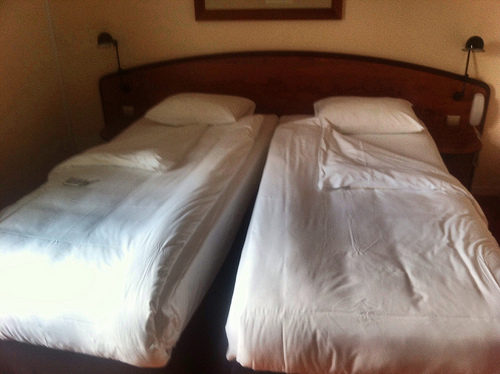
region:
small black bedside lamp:
[449, 21, 481, 106]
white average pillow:
[312, 95, 423, 145]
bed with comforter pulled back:
[287, 98, 450, 200]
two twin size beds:
[20, 66, 482, 363]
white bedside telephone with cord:
[461, 75, 483, 136]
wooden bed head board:
[90, 48, 499, 155]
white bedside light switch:
[441, 105, 461, 130]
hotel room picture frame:
[182, 2, 352, 27]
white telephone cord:
[467, 122, 494, 153]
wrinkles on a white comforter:
[414, 192, 491, 294]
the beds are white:
[24, 94, 483, 361]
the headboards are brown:
[76, 11, 460, 165]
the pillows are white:
[135, 80, 475, 165]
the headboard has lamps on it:
[73, 10, 495, 134]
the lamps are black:
[73, 22, 490, 161]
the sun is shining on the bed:
[3, 176, 183, 362]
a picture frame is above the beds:
[188, 0, 425, 57]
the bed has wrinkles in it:
[310, 168, 495, 310]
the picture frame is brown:
[190, 2, 435, 62]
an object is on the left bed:
[53, 159, 130, 219]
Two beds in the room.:
[5, 20, 495, 359]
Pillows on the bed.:
[144, 80, 421, 137]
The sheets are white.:
[2, 82, 494, 359]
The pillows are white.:
[137, 76, 436, 139]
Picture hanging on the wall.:
[180, 0, 359, 22]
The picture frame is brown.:
[188, 2, 346, 24]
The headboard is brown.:
[73, 32, 489, 162]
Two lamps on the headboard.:
[87, 14, 483, 79]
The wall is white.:
[5, 2, 107, 159]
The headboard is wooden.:
[87, 40, 492, 172]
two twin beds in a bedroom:
[6, 5, 498, 369]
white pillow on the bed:
[302, 91, 434, 136]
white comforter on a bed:
[262, 153, 487, 372]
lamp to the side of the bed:
[449, 23, 499, 85]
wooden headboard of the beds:
[147, 44, 452, 94]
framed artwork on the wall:
[179, 1, 366, 28]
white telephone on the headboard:
[468, 87, 489, 142]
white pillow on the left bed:
[149, 87, 254, 137]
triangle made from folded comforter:
[309, 129, 458, 205]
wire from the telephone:
[466, 129, 498, 164]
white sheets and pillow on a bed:
[271, 94, 498, 357]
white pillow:
[312, 95, 423, 135]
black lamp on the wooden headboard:
[448, 35, 484, 101]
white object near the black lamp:
[452, 34, 486, 130]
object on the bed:
[56, 171, 106, 191]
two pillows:
[141, 90, 428, 131]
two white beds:
[0, 93, 496, 366]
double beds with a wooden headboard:
[1, 52, 496, 367]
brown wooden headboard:
[95, 50, 493, 103]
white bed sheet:
[261, 127, 498, 348]